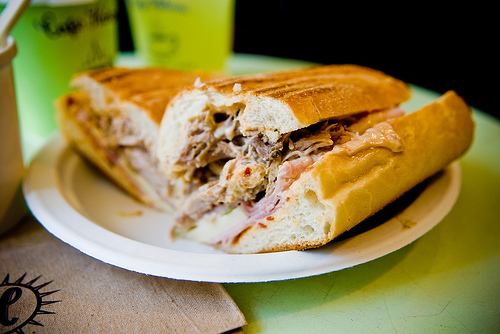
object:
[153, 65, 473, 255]
sandwich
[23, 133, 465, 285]
plate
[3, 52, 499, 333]
table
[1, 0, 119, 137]
cup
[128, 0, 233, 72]
cup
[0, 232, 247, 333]
napkin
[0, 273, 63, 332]
logo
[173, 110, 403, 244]
meat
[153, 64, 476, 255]
bread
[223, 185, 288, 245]
sauce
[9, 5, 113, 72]
drink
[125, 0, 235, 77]
drink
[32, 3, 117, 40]
writing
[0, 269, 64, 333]
star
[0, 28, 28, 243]
jar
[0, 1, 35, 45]
laddle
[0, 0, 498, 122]
background